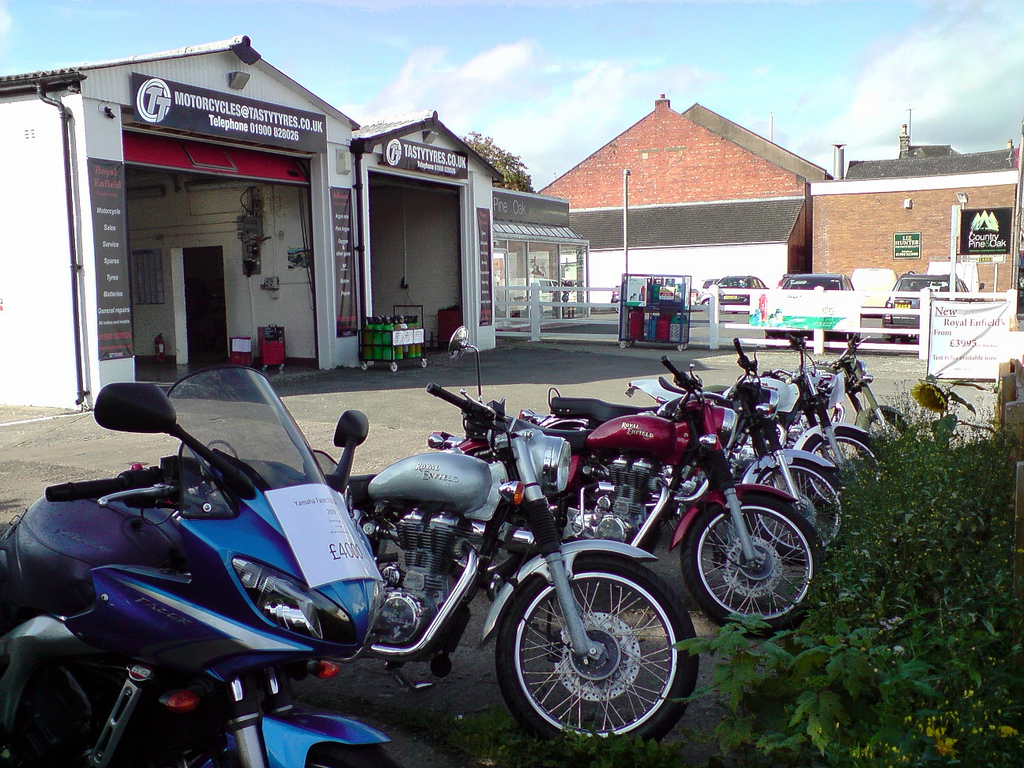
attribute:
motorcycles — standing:
[12, 360, 917, 757]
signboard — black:
[130, 65, 331, 152]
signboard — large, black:
[373, 127, 472, 188]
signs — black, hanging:
[82, 159, 507, 368]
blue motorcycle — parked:
[5, 381, 410, 756]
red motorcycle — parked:
[436, 368, 816, 622]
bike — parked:
[391, 437, 702, 748]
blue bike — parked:
[35, 419, 364, 765]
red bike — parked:
[577, 380, 824, 636]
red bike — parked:
[517, 400, 834, 616]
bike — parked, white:
[707, 346, 850, 550]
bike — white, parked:
[711, 282, 877, 480]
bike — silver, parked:
[378, 440, 669, 726]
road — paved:
[0, 365, 1013, 623]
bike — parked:
[441, 357, 827, 636]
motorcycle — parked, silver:
[341, 374, 696, 744]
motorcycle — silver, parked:
[443, 349, 826, 647]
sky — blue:
[271, 0, 1022, 65]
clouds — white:
[394, 33, 1015, 126]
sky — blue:
[10, 1, 1014, 180]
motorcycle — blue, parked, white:
[0, 367, 389, 766]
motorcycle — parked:
[5, 324, 914, 765]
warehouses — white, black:
[5, 35, 496, 408]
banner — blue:
[126, 70, 330, 160]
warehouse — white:
[0, 32, 368, 388]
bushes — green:
[825, 408, 1022, 763]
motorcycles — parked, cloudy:
[0, 327, 911, 762]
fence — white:
[500, 282, 1020, 371]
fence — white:
[506, 282, 1020, 352]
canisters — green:
[366, 310, 428, 361]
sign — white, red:
[743, 288, 864, 336]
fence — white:
[498, 288, 1023, 355]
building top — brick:
[530, 93, 825, 195]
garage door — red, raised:
[125, 131, 316, 189]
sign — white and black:
[129, 76, 335, 160]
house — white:
[21, 40, 527, 386]